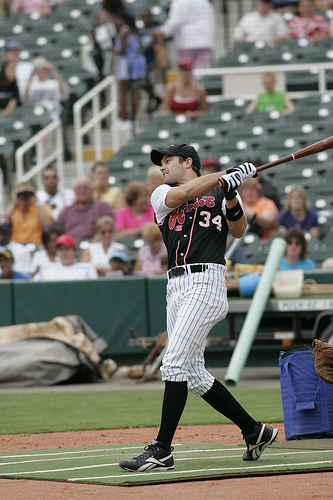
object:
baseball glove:
[312, 338, 333, 384]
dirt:
[0, 403, 332, 498]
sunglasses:
[39, 170, 66, 182]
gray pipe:
[223, 237, 286, 386]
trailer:
[219, 296, 332, 345]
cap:
[150, 143, 201, 170]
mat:
[0, 439, 333, 487]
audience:
[0, 0, 333, 298]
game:
[4, 129, 331, 491]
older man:
[56, 174, 115, 241]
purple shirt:
[56, 199, 114, 240]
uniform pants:
[156, 263, 231, 394]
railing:
[191, 63, 333, 105]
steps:
[59, 128, 103, 172]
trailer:
[159, 290, 321, 346]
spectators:
[3, 3, 332, 282]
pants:
[159, 262, 228, 398]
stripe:
[205, 269, 210, 296]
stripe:
[179, 333, 186, 348]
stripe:
[191, 362, 198, 380]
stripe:
[159, 340, 190, 383]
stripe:
[216, 298, 225, 312]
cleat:
[105, 442, 307, 481]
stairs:
[0, 115, 133, 291]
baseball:
[217, 135, 332, 188]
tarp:
[7, 312, 107, 392]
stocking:
[201, 378, 260, 436]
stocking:
[155, 381, 188, 447]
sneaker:
[241, 419, 279, 462]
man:
[118, 141, 279, 473]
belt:
[169, 264, 209, 279]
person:
[114, 182, 155, 230]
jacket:
[156, 1, 215, 52]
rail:
[72, 73, 120, 177]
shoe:
[119, 439, 176, 473]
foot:
[119, 439, 176, 474]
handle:
[283, 360, 323, 411]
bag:
[278, 339, 333, 441]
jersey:
[151, 185, 248, 270]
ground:
[0, 385, 284, 438]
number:
[199, 210, 223, 232]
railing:
[14, 118, 63, 196]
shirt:
[279, 254, 317, 270]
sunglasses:
[287, 241, 302, 248]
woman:
[233, 225, 319, 298]